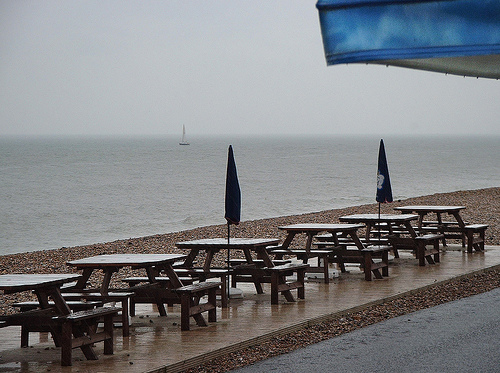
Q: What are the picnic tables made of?
A: Brown wood.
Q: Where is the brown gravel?
A: Between brown and gray platforms.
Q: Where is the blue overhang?
A: Upper right corner.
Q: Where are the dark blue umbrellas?
A: Between picnic tables.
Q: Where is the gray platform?
A: Right of brown gravel.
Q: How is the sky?
A: Gray, misty, cloudy.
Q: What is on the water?
A: A white fog.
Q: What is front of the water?
A: A rocky shore line.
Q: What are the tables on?
A: Concrete slab.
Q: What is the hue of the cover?
A: Blue and white.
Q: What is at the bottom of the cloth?
A: A seam.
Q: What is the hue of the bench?
A: Dark brown.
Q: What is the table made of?
A: Wooden planks.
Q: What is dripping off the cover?
A: Raindrops.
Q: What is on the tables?
A: Blue umbrellas.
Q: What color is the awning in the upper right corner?
A: Blue.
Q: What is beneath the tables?
A: A deck made from wooden boards.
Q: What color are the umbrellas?
A: Black.